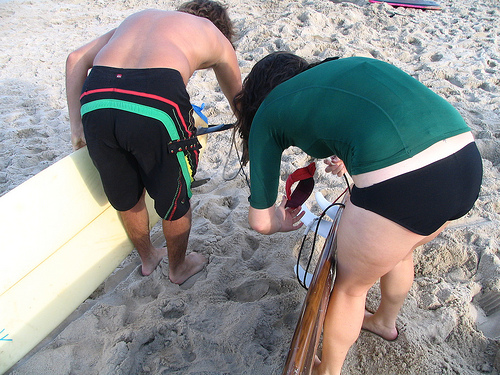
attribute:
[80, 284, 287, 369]
sand — tan, brown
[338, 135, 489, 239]
bottoms — black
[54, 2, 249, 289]
man — barefoot, shirtless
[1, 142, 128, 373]
surfboard — white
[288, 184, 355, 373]
surfboard — brown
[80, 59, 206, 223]
bottoms — striped